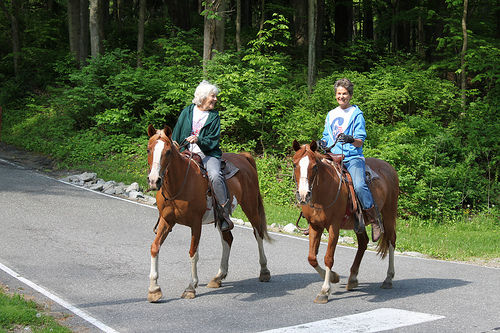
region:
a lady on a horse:
[139, 84, 271, 306]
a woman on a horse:
[289, 79, 398, 311]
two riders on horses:
[129, 74, 402, 307]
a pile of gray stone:
[75, 169, 142, 198]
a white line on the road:
[14, 244, 89, 329]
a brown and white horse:
[141, 131, 256, 311]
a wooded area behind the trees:
[65, 25, 160, 127]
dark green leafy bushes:
[77, 51, 153, 125]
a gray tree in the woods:
[305, 3, 323, 90]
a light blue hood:
[323, 107, 358, 165]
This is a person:
[312, 56, 383, 245]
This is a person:
[171, 72, 246, 242]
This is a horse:
[123, 123, 292, 308]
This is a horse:
[279, 136, 421, 304]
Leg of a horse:
[175, 215, 203, 305]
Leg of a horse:
[138, 212, 175, 309]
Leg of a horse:
[209, 214, 231, 299]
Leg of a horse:
[243, 205, 273, 287]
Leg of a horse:
[378, 208, 400, 303]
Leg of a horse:
[347, 225, 374, 306]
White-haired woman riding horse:
[171, 78, 234, 233]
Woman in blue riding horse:
[321, 78, 386, 243]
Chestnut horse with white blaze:
[145, 120, 277, 302]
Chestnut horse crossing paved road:
[290, 136, 400, 305]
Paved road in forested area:
[2, 157, 499, 331]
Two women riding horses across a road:
[145, 77, 400, 306]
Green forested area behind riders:
[1, 0, 498, 273]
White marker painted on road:
[254, 305, 447, 331]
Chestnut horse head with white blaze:
[289, 136, 319, 205]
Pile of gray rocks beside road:
[58, 170, 148, 200]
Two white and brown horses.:
[144, 124, 401, 299]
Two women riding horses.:
[122, 62, 416, 312]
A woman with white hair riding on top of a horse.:
[140, 72, 275, 306]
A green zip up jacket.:
[169, 105, 223, 158]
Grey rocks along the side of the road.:
[62, 169, 420, 256]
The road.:
[0, 151, 498, 331]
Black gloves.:
[317, 132, 353, 150]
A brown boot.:
[367, 207, 382, 242]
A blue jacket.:
[321, 107, 367, 161]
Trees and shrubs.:
[4, 2, 498, 269]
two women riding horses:
[147, 80, 400, 305]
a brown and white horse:
[143, 124, 274, 301]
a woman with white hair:
[191, 81, 219, 110]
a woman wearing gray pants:
[202, 152, 227, 204]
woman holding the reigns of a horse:
[325, 75, 367, 167]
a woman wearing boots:
[366, 204, 386, 240]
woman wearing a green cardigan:
[169, 103, 221, 162]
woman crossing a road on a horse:
[288, 74, 400, 302]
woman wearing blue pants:
[342, 155, 373, 211]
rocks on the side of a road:
[71, 172, 156, 204]